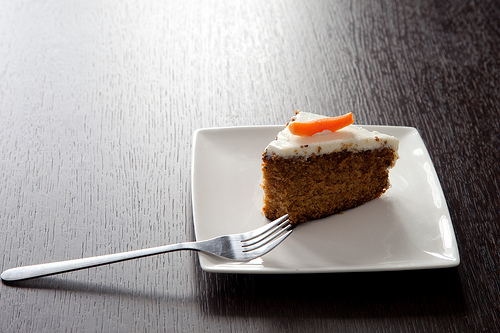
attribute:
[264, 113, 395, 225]
cake — small, brown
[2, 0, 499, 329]
table — brown, wooden, wood, black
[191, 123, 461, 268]
plate — white, square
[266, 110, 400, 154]
icing — white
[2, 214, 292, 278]
fork — silver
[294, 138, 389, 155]
crumbs — dark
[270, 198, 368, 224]
crust — dark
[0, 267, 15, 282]
edge — curved